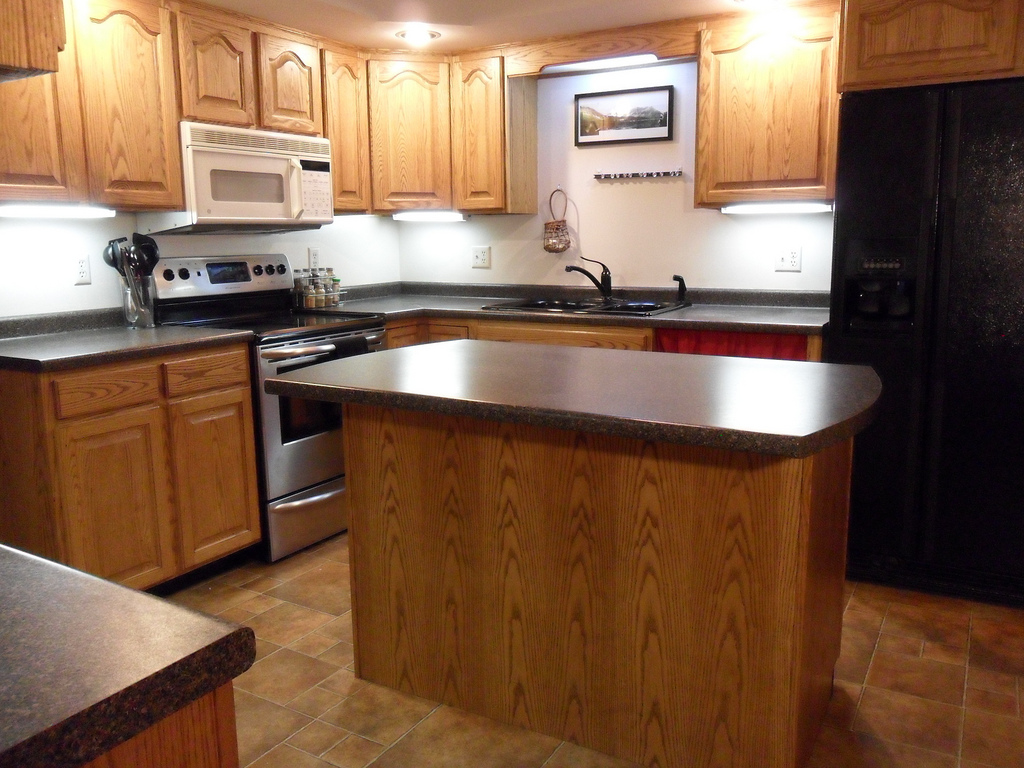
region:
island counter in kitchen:
[248, 309, 891, 766]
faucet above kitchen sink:
[557, 240, 625, 305]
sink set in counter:
[475, 281, 698, 321]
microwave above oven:
[120, 104, 346, 248]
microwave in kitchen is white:
[118, 109, 344, 240]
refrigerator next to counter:
[820, 72, 1021, 611]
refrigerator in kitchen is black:
[803, 81, 1020, 617]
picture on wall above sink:
[566, 81, 681, 158]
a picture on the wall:
[574, 93, 673, 138]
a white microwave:
[182, 127, 332, 219]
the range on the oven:
[155, 250, 356, 328]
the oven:
[261, 339, 383, 508]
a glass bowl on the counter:
[119, 279, 151, 321]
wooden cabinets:
[58, 374, 251, 559]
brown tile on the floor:
[216, 582, 362, 747]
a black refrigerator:
[826, 89, 1014, 555]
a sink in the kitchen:
[516, 256, 637, 323]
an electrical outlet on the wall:
[770, 238, 799, 270]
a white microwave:
[187, 136, 330, 214]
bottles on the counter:
[294, 262, 346, 301]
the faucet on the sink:
[562, 243, 619, 292]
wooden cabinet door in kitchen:
[444, 40, 502, 211]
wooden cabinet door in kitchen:
[365, 51, 452, 204]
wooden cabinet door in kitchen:
[253, 20, 320, 132]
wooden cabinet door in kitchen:
[68, 0, 180, 210]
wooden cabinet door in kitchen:
[0, 55, 87, 199]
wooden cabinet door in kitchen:
[696, 14, 834, 208]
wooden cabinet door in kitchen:
[52, 405, 179, 592]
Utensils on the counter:
[100, 231, 181, 330]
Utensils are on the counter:
[92, 220, 194, 338]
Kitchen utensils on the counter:
[84, 213, 180, 340]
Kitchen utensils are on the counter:
[95, 220, 176, 334]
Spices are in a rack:
[277, 261, 353, 313]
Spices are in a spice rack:
[285, 250, 356, 312]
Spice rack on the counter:
[291, 256, 350, 314]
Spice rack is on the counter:
[273, 261, 347, 316]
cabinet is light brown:
[369, 59, 453, 221]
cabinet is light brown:
[453, 52, 510, 217]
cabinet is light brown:
[698, 15, 841, 203]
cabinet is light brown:
[257, 30, 322, 133]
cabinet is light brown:
[172, 11, 259, 129]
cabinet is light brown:
[71, 2, 185, 209]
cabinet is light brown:
[169, 385, 264, 576]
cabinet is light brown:
[55, 406, 177, 588]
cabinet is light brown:
[58, 362, 164, 420]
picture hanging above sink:
[564, 81, 672, 152]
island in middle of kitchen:
[254, 309, 899, 766]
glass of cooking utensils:
[103, 231, 148, 329]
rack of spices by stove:
[285, 256, 343, 315]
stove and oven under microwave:
[131, 238, 400, 577]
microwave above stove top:
[121, 102, 331, 251]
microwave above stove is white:
[121, 126, 334, 245]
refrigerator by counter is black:
[806, 78, 1016, 616]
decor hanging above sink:
[538, 178, 571, 259]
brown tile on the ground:
[855, 667, 931, 741]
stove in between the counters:
[219, 297, 344, 335]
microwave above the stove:
[182, 118, 348, 218]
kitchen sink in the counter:
[511, 286, 680, 329]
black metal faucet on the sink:
[567, 256, 609, 289]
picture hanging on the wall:
[564, 82, 689, 153]